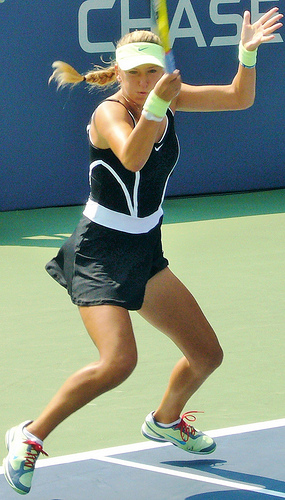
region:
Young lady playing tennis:
[4, 3, 282, 493]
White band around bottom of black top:
[72, 193, 166, 232]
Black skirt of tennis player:
[43, 213, 168, 310]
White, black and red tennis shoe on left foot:
[139, 413, 214, 455]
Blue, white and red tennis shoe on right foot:
[0, 416, 42, 494]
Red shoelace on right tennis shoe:
[20, 435, 49, 467]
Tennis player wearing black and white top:
[85, 93, 178, 230]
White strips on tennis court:
[2, 414, 280, 491]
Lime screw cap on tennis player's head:
[112, 40, 166, 69]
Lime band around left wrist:
[230, 43, 260, 69]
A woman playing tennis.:
[1, 3, 229, 492]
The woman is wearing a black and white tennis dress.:
[30, 89, 179, 301]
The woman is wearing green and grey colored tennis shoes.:
[0, 403, 219, 492]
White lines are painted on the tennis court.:
[1, 415, 278, 489]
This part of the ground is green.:
[195, 244, 262, 291]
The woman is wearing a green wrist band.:
[142, 82, 173, 126]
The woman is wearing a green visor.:
[108, 22, 177, 87]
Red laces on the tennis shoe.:
[16, 439, 48, 469]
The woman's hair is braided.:
[39, 24, 114, 94]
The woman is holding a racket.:
[133, 0, 195, 89]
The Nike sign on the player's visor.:
[134, 43, 149, 55]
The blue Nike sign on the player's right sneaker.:
[170, 433, 187, 448]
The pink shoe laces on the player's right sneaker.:
[179, 408, 206, 446]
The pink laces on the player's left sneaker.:
[24, 435, 42, 469]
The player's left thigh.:
[74, 300, 137, 368]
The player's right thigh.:
[149, 271, 218, 341]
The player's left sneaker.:
[5, 416, 53, 499]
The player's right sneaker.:
[143, 407, 217, 457]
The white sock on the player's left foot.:
[22, 429, 46, 446]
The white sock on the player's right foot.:
[161, 417, 178, 427]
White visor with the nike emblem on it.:
[111, 39, 169, 73]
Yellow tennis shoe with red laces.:
[138, 410, 222, 461]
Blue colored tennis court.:
[57, 460, 131, 494]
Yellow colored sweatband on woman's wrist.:
[133, 85, 176, 125]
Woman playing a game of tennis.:
[24, 5, 259, 474]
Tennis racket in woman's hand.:
[142, 0, 185, 101]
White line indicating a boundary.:
[219, 410, 283, 440]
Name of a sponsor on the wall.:
[69, 2, 282, 54]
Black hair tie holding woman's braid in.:
[77, 71, 88, 82]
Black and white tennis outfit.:
[45, 98, 194, 317]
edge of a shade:
[199, 204, 225, 226]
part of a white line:
[131, 452, 155, 483]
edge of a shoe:
[199, 441, 216, 454]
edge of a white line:
[74, 455, 109, 472]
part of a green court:
[111, 398, 128, 422]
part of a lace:
[176, 413, 190, 433]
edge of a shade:
[194, 490, 211, 498]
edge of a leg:
[156, 390, 171, 420]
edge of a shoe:
[143, 414, 152, 430]